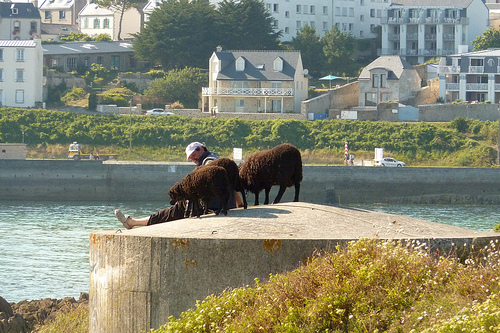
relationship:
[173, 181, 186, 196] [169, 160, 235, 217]
neck of a sheep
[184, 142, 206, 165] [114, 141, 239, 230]
head of man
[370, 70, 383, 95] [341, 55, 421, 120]
glass window on building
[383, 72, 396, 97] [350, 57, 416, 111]
window on building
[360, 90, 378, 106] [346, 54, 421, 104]
window of building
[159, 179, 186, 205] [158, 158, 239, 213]
head of sheep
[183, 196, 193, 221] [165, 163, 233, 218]
leg belonging to sheep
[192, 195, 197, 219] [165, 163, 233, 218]
leg belonging to sheep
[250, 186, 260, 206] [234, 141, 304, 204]
leg belonging to sheep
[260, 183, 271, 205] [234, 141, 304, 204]
leg belonging to sheep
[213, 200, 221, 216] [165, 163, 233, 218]
leg belonging to sheep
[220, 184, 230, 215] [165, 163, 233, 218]
leg belonging to sheep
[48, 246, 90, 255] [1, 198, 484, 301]
ripple formed in river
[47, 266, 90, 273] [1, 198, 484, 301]
ripple formed in river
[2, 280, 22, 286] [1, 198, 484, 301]
ripple formed in river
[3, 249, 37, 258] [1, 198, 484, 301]
ripple formed in river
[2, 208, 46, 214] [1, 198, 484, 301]
ripple formed in river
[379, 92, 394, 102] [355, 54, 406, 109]
window belonging to building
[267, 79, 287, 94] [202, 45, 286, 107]
window belonging to building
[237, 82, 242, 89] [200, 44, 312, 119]
window belonging to building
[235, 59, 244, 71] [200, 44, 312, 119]
window belonging to building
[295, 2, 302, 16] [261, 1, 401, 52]
window belonging to building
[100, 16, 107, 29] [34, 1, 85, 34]
window belonging to building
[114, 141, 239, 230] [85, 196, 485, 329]
man sitting on pier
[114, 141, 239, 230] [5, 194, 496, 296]
man sitting close to river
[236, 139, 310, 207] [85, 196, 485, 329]
sheep standing on pier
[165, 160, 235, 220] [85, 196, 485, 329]
sheep standing on pier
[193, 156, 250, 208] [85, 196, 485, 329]
sheep standing on pier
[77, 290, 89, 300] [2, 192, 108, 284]
rock lying next to water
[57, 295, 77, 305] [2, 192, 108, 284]
rock lying next to water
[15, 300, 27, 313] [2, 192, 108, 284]
rock lying next to water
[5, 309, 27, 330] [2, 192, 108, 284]
rock lying next to water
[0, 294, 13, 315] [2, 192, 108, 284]
rock lying next to water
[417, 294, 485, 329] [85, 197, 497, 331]
weed growing next to cement pier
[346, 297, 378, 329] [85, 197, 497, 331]
weed growing next to cement pier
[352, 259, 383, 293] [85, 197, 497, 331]
weed growing next to cement pier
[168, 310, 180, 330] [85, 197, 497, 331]
weed growing next to cement pier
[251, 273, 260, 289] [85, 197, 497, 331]
weed growing next to cement pier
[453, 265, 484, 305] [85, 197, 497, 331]
brush growing next to cement pier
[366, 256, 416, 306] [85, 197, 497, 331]
brush growing next to cement pier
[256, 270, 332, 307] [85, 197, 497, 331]
brush growing next to cement pier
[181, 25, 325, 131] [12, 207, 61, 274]
house standing across river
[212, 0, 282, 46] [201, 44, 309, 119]
trees standing behind house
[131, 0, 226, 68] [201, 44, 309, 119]
trees standing behind house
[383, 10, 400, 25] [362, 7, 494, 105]
balcony attached to building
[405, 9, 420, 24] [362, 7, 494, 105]
balcony attached to building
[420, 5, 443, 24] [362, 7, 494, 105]
balcony attached to building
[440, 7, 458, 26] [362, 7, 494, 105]
balcony attached to building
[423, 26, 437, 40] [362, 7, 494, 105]
balcony attached to building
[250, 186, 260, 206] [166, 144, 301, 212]
leg on back end of sheep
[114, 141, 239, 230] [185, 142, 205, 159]
man wears a hat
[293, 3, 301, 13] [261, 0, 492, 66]
window on a building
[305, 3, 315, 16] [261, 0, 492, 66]
window on a building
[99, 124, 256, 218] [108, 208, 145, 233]
man wearing a shoe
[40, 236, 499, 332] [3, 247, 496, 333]
grass on ground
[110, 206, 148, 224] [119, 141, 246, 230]
foot of a person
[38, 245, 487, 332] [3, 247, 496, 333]
grass on ground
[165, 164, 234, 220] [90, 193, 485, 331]
sheep is beside ledge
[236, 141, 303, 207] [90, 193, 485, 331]
sheep is beside ledge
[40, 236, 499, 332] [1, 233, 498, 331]
grass on ground